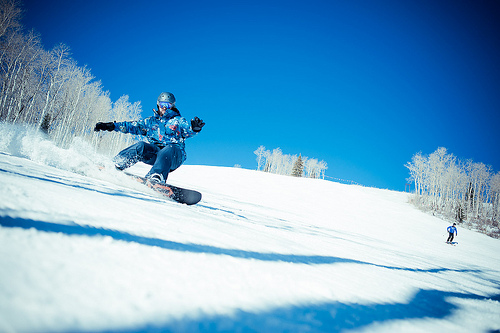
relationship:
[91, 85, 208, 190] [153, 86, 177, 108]
person wearing helmet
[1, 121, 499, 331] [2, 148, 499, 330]
snow on ground